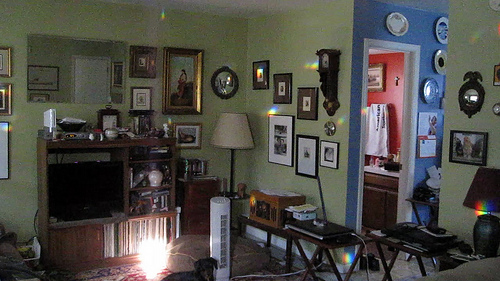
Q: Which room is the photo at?
A: It is at the living room.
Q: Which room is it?
A: It is a living room.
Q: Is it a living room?
A: Yes, it is a living room.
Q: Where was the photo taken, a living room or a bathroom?
A: It was taken at a living room.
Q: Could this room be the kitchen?
A: No, it is the living room.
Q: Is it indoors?
A: Yes, it is indoors.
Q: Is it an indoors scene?
A: Yes, it is indoors.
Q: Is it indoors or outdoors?
A: It is indoors.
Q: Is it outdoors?
A: No, it is indoors.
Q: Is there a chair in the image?
A: No, there are no chairs.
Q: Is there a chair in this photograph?
A: No, there are no chairs.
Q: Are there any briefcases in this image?
A: No, there are no briefcases.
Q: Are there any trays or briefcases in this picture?
A: No, there are no briefcases or trays.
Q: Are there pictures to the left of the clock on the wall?
A: Yes, there is a picture to the left of the clock.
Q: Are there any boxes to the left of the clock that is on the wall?
A: No, there is a picture to the left of the clock.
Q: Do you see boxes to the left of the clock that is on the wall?
A: No, there is a picture to the left of the clock.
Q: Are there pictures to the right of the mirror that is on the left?
A: Yes, there is a picture to the right of the mirror.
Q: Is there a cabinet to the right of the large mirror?
A: No, there is a picture to the right of the mirror.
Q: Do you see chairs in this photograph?
A: No, there are no chairs.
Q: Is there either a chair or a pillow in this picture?
A: No, there are no chairs or pillows.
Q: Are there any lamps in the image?
A: Yes, there is a lamp.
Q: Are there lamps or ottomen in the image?
A: Yes, there is a lamp.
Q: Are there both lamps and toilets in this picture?
A: No, there is a lamp but no toilets.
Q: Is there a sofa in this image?
A: No, there are no sofas.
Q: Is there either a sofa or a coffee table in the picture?
A: No, there are no sofas or coffee tables.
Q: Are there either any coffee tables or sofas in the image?
A: No, there are no sofas or coffee tables.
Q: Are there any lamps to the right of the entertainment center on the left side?
A: Yes, there is a lamp to the right of the entertainment center.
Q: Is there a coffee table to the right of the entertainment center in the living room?
A: No, there is a lamp to the right of the entertainment center.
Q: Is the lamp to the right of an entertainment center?
A: Yes, the lamp is to the right of an entertainment center.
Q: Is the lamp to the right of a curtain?
A: No, the lamp is to the right of an entertainment center.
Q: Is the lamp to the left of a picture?
A: Yes, the lamp is to the left of a picture.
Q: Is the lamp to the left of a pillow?
A: No, the lamp is to the left of a picture.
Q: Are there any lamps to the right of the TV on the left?
A: Yes, there is a lamp to the right of the TV.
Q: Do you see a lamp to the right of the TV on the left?
A: Yes, there is a lamp to the right of the TV.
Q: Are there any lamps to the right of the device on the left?
A: Yes, there is a lamp to the right of the TV.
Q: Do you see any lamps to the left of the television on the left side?
A: No, the lamp is to the right of the television.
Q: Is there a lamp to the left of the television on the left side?
A: No, the lamp is to the right of the television.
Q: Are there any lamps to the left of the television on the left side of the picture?
A: No, the lamp is to the right of the television.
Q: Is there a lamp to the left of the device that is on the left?
A: No, the lamp is to the right of the television.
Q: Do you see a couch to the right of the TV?
A: No, there is a lamp to the right of the TV.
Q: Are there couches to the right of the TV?
A: No, there is a lamp to the right of the TV.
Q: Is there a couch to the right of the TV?
A: No, there is a lamp to the right of the TV.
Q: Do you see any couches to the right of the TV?
A: No, there is a lamp to the right of the TV.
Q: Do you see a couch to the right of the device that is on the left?
A: No, there is a lamp to the right of the TV.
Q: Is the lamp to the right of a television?
A: Yes, the lamp is to the right of a television.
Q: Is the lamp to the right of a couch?
A: No, the lamp is to the right of a television.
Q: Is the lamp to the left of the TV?
A: No, the lamp is to the right of the TV.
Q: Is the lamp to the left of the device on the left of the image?
A: No, the lamp is to the right of the TV.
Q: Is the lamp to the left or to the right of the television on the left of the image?
A: The lamp is to the right of the TV.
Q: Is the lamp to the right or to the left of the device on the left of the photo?
A: The lamp is to the right of the TV.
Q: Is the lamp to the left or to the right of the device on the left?
A: The lamp is to the right of the TV.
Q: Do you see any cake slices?
A: No, there are no cake slices.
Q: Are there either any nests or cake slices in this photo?
A: No, there are no cake slices or nests.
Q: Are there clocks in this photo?
A: Yes, there is a clock.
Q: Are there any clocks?
A: Yes, there is a clock.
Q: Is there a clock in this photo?
A: Yes, there is a clock.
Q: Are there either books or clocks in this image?
A: Yes, there is a clock.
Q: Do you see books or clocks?
A: Yes, there is a clock.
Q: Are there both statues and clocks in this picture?
A: No, there is a clock but no statues.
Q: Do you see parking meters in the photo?
A: No, there are no parking meters.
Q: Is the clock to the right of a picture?
A: Yes, the clock is to the right of a picture.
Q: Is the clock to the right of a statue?
A: No, the clock is to the right of a picture.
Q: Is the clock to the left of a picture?
A: No, the clock is to the right of a picture.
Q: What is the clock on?
A: The clock is on the wall.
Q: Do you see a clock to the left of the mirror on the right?
A: Yes, there is a clock to the left of the mirror.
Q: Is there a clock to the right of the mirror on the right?
A: No, the clock is to the left of the mirror.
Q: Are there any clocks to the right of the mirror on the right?
A: No, the clock is to the left of the mirror.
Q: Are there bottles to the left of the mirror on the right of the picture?
A: No, there is a clock to the left of the mirror.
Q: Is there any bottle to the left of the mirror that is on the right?
A: No, there is a clock to the left of the mirror.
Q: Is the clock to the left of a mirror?
A: Yes, the clock is to the left of a mirror.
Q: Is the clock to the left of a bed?
A: No, the clock is to the left of a mirror.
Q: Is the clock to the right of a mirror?
A: No, the clock is to the left of a mirror.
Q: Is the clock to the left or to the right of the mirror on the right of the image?
A: The clock is to the left of the mirror.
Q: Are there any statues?
A: No, there are no statues.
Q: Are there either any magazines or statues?
A: No, there are no statues or magazines.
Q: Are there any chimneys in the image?
A: No, there are no chimneys.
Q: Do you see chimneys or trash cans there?
A: No, there are no chimneys or trash cans.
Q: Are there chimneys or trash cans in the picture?
A: No, there are no chimneys or trash cans.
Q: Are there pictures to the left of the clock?
A: Yes, there is a picture to the left of the clock.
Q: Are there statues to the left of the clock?
A: No, there is a picture to the left of the clock.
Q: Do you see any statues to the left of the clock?
A: No, there is a picture to the left of the clock.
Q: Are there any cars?
A: No, there are no cars.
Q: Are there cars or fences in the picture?
A: No, there are no cars or fences.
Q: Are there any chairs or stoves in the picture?
A: No, there are no chairs or stoves.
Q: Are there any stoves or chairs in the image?
A: No, there are no chairs or stoves.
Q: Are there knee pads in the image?
A: No, there are no knee pads.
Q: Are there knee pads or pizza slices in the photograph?
A: No, there are no knee pads or pizza slices.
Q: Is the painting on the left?
A: Yes, the painting is on the left of the image.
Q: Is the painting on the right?
A: No, the painting is on the left of the image.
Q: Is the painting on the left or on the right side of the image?
A: The painting is on the left of the image.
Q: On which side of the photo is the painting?
A: The painting is on the left of the image.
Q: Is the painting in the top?
A: Yes, the painting is in the top of the image.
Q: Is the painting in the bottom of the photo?
A: No, the painting is in the top of the image.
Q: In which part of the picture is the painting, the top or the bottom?
A: The painting is in the top of the image.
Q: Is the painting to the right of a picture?
A: No, the painting is to the left of a picture.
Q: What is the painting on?
A: The painting is on the wall.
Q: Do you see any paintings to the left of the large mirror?
A: Yes, there is a painting to the left of the mirror.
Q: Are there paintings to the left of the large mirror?
A: Yes, there is a painting to the left of the mirror.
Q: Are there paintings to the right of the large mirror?
A: No, the painting is to the left of the mirror.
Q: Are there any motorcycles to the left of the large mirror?
A: No, there is a painting to the left of the mirror.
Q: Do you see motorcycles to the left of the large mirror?
A: No, there is a painting to the left of the mirror.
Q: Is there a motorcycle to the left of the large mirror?
A: No, there is a painting to the left of the mirror.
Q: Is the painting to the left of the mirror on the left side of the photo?
A: Yes, the painting is to the left of the mirror.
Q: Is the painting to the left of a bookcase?
A: No, the painting is to the left of the mirror.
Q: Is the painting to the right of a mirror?
A: No, the painting is to the left of a mirror.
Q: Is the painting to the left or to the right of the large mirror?
A: The painting is to the left of the mirror.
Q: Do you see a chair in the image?
A: No, there are no chairs.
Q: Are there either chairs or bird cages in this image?
A: No, there are no chairs or bird cages.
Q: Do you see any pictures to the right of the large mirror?
A: Yes, there is a picture to the right of the mirror.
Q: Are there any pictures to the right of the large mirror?
A: Yes, there is a picture to the right of the mirror.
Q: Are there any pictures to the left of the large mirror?
A: No, the picture is to the right of the mirror.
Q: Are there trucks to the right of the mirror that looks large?
A: No, there is a picture to the right of the mirror.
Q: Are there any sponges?
A: No, there are no sponges.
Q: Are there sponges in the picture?
A: No, there are no sponges.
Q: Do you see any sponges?
A: No, there are no sponges.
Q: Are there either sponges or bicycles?
A: No, there are no sponges or bicycles.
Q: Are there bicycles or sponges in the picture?
A: No, there are no sponges or bicycles.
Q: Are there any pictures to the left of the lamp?
A: Yes, there is a picture to the left of the lamp.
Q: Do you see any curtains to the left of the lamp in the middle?
A: No, there is a picture to the left of the lamp.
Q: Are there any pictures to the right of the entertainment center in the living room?
A: Yes, there is a picture to the right of the entertainment center.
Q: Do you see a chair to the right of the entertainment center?
A: No, there is a picture to the right of the entertainment center.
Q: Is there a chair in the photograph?
A: No, there are no chairs.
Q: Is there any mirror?
A: Yes, there is a mirror.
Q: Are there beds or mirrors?
A: Yes, there is a mirror.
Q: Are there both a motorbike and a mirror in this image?
A: No, there is a mirror but no motorcycles.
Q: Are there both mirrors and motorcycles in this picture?
A: No, there is a mirror but no motorcycles.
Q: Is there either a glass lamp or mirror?
A: Yes, there is a glass mirror.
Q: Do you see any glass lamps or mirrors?
A: Yes, there is a glass mirror.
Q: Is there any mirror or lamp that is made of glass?
A: Yes, the mirror is made of glass.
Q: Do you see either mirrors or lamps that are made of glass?
A: Yes, the mirror is made of glass.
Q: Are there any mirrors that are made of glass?
A: Yes, there is a mirror that is made of glass.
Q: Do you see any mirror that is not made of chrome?
A: Yes, there is a mirror that is made of glass.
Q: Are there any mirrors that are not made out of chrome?
A: Yes, there is a mirror that is made of glass.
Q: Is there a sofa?
A: No, there are no sofas.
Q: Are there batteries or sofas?
A: No, there are no sofas or batteries.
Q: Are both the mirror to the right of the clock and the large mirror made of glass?
A: Yes, both the mirror and the mirror are made of glass.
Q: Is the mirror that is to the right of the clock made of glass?
A: Yes, the mirror is made of glass.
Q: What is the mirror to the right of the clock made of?
A: The mirror is made of glass.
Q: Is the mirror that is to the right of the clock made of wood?
A: No, the mirror is made of glass.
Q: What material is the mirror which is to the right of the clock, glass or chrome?
A: The mirror is made of glass.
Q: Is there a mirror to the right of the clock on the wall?
A: Yes, there is a mirror to the right of the clock.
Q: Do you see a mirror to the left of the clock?
A: No, the mirror is to the right of the clock.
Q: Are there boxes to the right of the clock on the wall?
A: No, there is a mirror to the right of the clock.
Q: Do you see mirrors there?
A: Yes, there is a mirror.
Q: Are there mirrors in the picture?
A: Yes, there is a mirror.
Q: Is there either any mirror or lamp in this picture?
A: Yes, there is a mirror.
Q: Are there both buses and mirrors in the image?
A: No, there is a mirror but no buses.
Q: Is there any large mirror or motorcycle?
A: Yes, there is a large mirror.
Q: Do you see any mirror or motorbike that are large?
A: Yes, the mirror is large.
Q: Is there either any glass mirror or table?
A: Yes, there is a glass mirror.